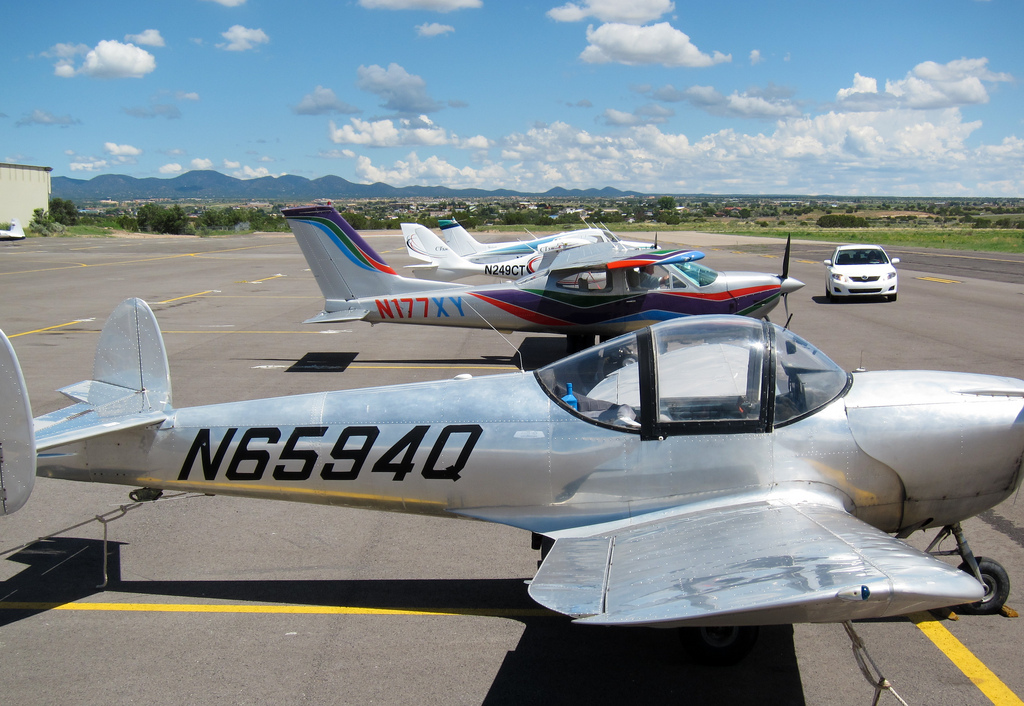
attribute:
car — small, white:
[828, 228, 905, 334]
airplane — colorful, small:
[264, 198, 797, 345]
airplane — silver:
[17, 266, 1016, 631]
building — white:
[0, 164, 57, 234]